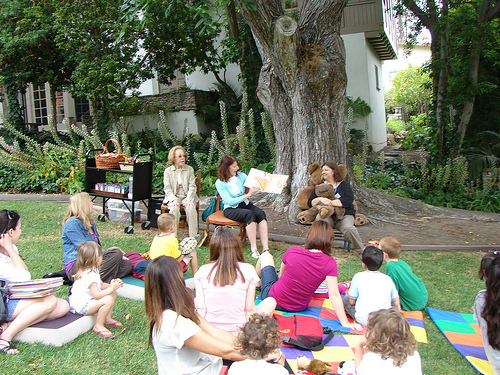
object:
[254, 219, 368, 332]
people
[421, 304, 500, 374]
blankets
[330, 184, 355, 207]
arms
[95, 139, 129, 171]
basket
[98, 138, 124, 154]
handle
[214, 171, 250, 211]
sweater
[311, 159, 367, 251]
lady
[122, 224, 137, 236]
wheels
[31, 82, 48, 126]
window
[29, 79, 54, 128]
panes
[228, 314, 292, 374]
child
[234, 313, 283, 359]
hair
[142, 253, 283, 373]
people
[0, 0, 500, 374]
outside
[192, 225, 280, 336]
adults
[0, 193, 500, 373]
ground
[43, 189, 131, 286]
adults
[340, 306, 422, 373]
children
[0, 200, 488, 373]
grass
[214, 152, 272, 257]
lady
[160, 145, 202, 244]
woman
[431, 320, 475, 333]
square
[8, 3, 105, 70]
leaves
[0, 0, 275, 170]
trees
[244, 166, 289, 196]
book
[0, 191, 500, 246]
dirt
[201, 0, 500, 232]
tree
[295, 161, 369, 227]
bear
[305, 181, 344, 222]
bear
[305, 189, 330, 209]
arm's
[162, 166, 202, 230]
chair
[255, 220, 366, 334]
girl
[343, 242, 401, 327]
boy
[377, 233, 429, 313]
boys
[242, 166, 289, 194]
story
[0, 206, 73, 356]
woman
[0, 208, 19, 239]
hair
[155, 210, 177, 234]
hair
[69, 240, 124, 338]
child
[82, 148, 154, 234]
cart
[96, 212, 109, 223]
wheels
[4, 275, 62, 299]
books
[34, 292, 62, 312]
lap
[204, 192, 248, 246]
chairs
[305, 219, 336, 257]
hair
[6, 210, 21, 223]
sunglasses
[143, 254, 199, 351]
hair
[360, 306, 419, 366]
hair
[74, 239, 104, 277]
hair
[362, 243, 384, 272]
hair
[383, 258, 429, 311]
shirt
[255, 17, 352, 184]
trunk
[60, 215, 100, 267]
shirt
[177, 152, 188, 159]
sunglasses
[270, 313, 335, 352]
backpack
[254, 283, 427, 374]
blanket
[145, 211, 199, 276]
boy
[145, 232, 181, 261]
shirt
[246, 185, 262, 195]
hand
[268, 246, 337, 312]
shirt